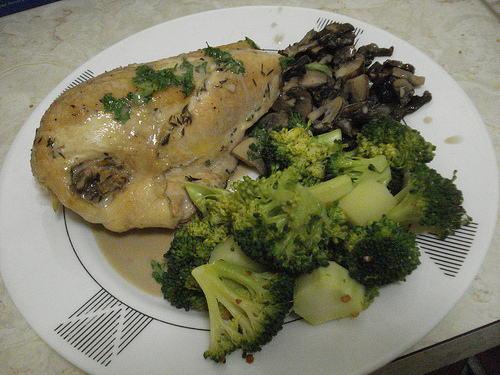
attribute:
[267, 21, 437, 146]
mushrooms — cooked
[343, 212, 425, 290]
floret — dark green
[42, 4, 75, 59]
vein — light brown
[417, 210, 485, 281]
design — black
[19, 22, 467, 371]
plate — white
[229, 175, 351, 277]
broccoli — green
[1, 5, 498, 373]
plate — white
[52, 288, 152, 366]
design — black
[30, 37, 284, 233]
chicken breast — seasoned, big, brown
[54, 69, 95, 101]
design — black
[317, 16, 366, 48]
design — black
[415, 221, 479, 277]
design — black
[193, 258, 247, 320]
stem — green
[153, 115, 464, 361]
broccoli — green, cooked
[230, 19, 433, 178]
mushrooms — sauteed, cooked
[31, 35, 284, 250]
chicken — herbal, baked, brown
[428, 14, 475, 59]
counter top — beige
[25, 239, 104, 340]
plate — white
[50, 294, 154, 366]
pattern — short lines, long lines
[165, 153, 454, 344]
broccoli — cut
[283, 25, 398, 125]
mushrooms — cut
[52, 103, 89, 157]
skin — browned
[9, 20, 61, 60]
tabletop — stone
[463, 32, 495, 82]
table — brown